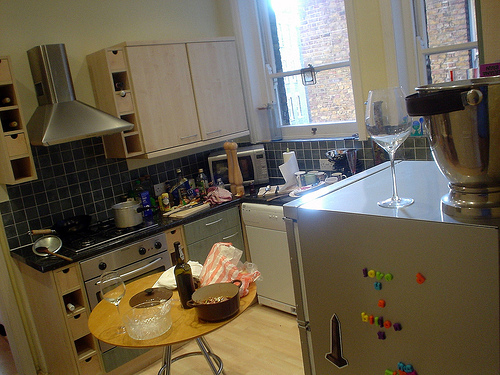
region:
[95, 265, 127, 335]
A wine glass on the table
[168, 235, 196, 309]
A wine glass on a table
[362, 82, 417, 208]
A wine glass on the refrigerator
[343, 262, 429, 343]
Magnets on a refrigerator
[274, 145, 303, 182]
A paper towel on a counter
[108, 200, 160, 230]
A kettle on a stove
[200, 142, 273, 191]
A silver microwave on a counter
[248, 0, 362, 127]
A window looking out into the street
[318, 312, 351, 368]
A dark blue magnet on the side of a refrigerator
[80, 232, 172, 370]
A silver stove and oven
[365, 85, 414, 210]
a cloudy looking wineglass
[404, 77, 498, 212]
a metal ice bucket with a black handle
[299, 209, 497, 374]
letter-shaped magnets on the side of a refrigerator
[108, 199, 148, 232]
large metal pot on a stove burner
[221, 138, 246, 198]
tall wooden salt and pepper mills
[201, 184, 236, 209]
a pink rag on a counter-top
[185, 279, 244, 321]
brown pot on a table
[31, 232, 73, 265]
wooden spoon resting in an overturned pot lid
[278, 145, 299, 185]
roll of white paper towels in a standing holder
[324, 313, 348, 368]
a monument-shaped magnet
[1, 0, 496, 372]
A close snap of a beautiful kitchen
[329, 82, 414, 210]
An visible wine glass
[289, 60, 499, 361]
Wine glass and a jar is placed on the top a refrigerator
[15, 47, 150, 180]
Chimney is fixed on the wall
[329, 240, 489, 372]
different color stickies are plaed in the refrigerator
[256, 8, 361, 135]
A beautiful window made up of glass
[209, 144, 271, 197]
Owen is placed in the kitchen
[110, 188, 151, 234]
A pressure cooker is placed on the stove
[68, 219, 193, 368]
A solid plated stainless steel stove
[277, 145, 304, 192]
Tissue paper is placed near the owen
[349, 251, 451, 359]
Different types of letters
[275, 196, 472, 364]
Different type of letters on the fridge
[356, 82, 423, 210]
A wine glass on the fridge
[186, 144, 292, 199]
A oven in the corner of the kichten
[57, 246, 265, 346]
A brown color table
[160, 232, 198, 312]
A wine bottle on the table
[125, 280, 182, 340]
A glass bowl on the table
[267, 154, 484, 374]
A fridge in the kitchen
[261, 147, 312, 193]
Tissue paper near the oven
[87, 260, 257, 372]
A small round brown and silver table.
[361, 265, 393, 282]
The word love written in magnets.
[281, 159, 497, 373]
A white fridge with magnets on the side.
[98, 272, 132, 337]
An empty wine glass on the edge of a brown table.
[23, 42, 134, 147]
A silver hood vent above a stove.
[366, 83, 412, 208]
A clear empty wine glass on top of the fridge.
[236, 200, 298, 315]
A white dishwasher.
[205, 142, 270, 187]
A silver microwave in the corner.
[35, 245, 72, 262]
A wooden spoon sitting in the inside of a silver lid.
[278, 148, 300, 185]
A roll of white paper towels.